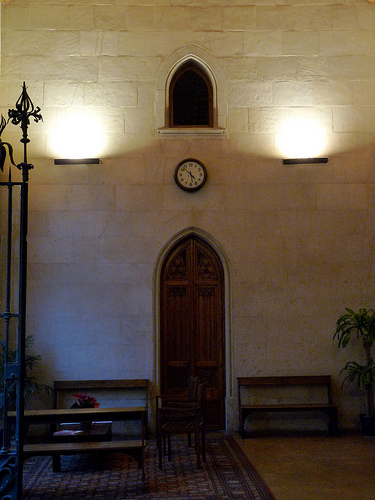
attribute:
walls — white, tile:
[9, 4, 375, 431]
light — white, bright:
[39, 94, 114, 170]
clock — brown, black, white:
[171, 157, 215, 193]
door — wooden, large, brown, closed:
[157, 230, 229, 432]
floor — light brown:
[252, 428, 374, 498]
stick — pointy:
[10, 76, 40, 499]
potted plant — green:
[324, 308, 375, 441]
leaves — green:
[332, 304, 375, 396]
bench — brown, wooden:
[234, 372, 339, 432]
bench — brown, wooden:
[46, 375, 153, 440]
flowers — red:
[66, 391, 101, 408]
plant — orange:
[70, 391, 102, 430]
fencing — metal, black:
[1, 80, 29, 499]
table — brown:
[49, 409, 115, 458]